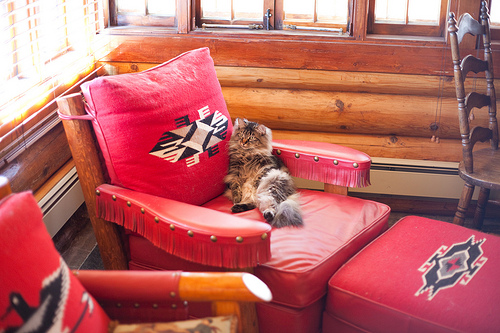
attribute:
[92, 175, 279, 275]
fringe — red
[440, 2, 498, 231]
wood chair — brown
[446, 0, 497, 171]
chair back — tall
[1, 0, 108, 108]
window — sunny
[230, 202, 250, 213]
cat paw — small, black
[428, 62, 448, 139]
string — brown, pull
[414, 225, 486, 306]
pattern — southwestern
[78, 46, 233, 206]
cushion — bright red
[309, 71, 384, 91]
knoll — wood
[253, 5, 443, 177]
house — log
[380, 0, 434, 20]
window — narrow, wooden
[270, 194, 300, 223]
tail — fluffy, gray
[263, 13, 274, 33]
latch — metal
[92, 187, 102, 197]
nail — brass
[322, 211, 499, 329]
ottoman — bright red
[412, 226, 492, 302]
design — southwest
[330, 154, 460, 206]
baseboard — tan, heater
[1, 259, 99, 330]
bird design — black, white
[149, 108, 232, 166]
design — southwest